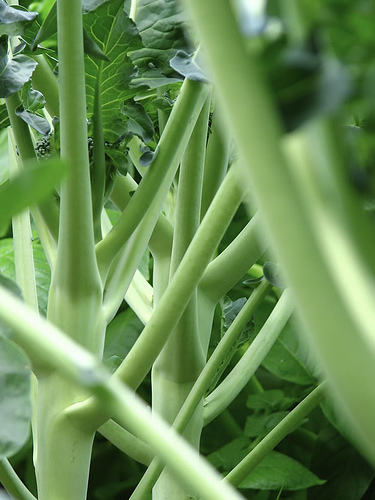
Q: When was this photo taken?
A: During the day.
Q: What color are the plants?
A: Green.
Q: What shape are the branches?
A: Cylindrical.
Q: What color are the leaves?
A: Dark green.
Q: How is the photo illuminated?
A: Sunlight.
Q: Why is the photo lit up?
A: From the sun.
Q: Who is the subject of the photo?
A: The plants.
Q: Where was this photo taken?
A: In the garden.